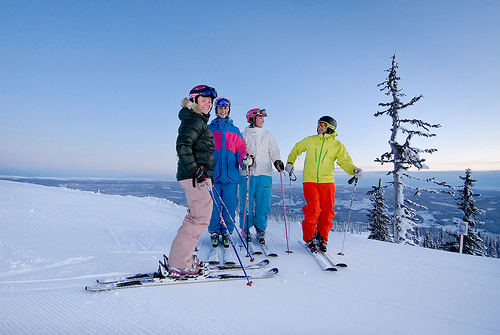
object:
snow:
[0, 178, 499, 331]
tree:
[375, 48, 435, 245]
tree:
[447, 168, 487, 252]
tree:
[366, 177, 391, 244]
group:
[153, 84, 354, 282]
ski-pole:
[280, 170, 291, 254]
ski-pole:
[241, 168, 251, 250]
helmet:
[245, 108, 266, 119]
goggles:
[256, 108, 268, 117]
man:
[282, 115, 369, 252]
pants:
[301, 182, 337, 241]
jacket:
[288, 133, 357, 183]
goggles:
[318, 121, 328, 128]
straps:
[329, 124, 337, 132]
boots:
[169, 257, 202, 279]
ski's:
[82, 260, 280, 292]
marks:
[0, 265, 135, 298]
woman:
[167, 85, 216, 275]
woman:
[211, 96, 243, 244]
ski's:
[207, 242, 238, 265]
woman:
[242, 109, 279, 243]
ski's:
[246, 235, 276, 256]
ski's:
[300, 237, 348, 273]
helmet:
[316, 115, 337, 132]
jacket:
[212, 117, 245, 184]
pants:
[207, 181, 237, 237]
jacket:
[169, 102, 213, 180]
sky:
[2, 1, 500, 176]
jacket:
[244, 125, 284, 175]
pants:
[167, 178, 215, 274]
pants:
[241, 175, 273, 236]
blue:
[210, 118, 249, 236]